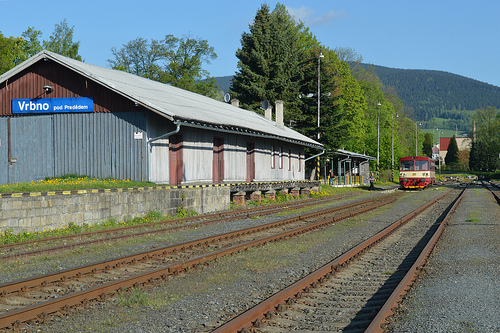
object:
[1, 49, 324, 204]
building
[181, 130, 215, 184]
doors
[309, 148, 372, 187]
building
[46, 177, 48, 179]
flower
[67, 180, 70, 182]
flower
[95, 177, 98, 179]
flower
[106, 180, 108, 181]
flower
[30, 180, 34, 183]
flower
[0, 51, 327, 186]
barn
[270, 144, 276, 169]
window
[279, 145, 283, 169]
window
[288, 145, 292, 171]
window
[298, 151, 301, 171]
window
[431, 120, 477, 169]
building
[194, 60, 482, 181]
background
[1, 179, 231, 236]
wall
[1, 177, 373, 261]
track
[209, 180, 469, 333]
track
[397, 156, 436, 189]
train car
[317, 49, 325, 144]
security light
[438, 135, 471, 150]
roof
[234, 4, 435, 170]
row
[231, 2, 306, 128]
tree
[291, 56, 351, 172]
tree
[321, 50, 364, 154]
tree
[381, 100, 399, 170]
tree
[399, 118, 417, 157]
tree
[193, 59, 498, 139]
hillside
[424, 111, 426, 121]
tree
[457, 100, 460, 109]
tree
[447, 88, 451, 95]
tree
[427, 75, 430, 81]
tree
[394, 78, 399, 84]
tree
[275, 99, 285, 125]
chimney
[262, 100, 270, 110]
satellite dish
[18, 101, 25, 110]
letter v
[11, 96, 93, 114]
sign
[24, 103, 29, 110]
letter r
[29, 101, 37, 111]
letter b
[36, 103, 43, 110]
letter n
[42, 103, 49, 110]
letter o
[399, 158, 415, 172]
window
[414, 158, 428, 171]
right window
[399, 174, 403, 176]
headlight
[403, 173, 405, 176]
headlight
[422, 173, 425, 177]
headlight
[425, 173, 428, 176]
headlight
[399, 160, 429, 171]
front windshield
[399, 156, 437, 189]
train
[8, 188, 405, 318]
track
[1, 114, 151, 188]
aluminum siding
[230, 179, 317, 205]
porch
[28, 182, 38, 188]
flowers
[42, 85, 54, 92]
light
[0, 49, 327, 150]
roof